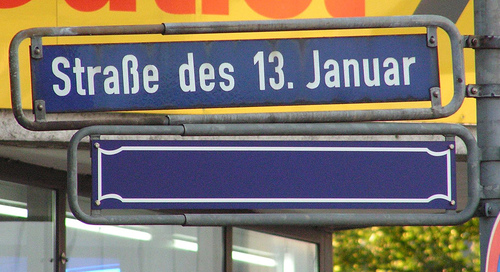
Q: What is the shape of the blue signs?
A: Rectangle.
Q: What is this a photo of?
A: Street sign.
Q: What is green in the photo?
A: Tree leaves.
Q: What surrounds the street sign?
A: Metal pole.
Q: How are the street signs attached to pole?
A: Screws,.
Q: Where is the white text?
A: On signs.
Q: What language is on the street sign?
A: Portuguese.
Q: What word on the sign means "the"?
A: Des.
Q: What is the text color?
A: White.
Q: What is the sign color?
A: Blue.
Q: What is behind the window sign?
A: A road sign.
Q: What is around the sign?
A: Gray bar.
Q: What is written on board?
A: Letters.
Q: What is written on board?
A: Letters.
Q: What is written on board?
A: Text.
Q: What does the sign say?
A: Strabe des 13. Januar.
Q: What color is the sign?
A: Blue.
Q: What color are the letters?
A: White.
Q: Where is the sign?
A: Up on a post.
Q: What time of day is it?
A: Daytime.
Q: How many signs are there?
A: One.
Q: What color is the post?
A: Gray.